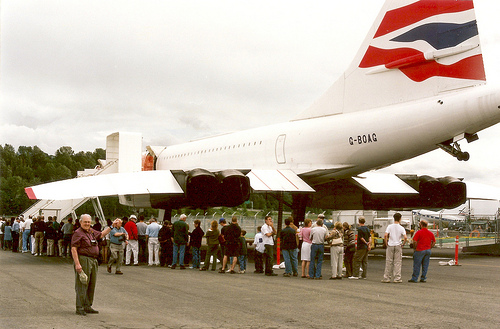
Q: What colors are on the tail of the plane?
A: Red and blue.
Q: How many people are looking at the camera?
A: 1.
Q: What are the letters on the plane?
A: Q-BOAG.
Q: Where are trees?
A: Behind plane.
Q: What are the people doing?
A: Waiting.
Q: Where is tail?
A: On airplane.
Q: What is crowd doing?
A: Waiting.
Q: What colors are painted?
A: Red and blue.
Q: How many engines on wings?
A: Four.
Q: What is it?
A: Airplane.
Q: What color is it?
A: White.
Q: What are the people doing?
A: Standing.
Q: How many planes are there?
A: One.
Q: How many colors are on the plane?
A: Three.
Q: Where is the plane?
A: On runway.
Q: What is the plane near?
A: Fence.